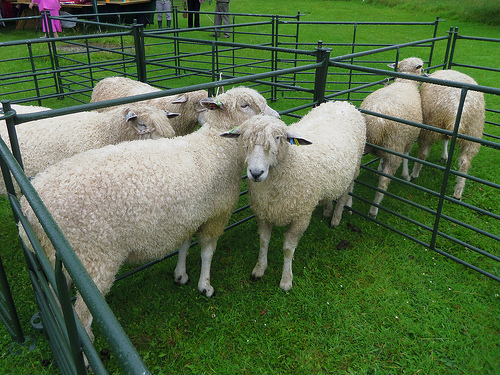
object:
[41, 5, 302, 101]
cage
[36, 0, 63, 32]
dress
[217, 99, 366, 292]
sheep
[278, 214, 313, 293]
front legs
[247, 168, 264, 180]
nose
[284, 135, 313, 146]
ear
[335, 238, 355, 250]
manure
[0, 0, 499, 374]
grass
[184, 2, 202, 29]
pants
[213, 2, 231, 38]
pants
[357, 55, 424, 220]
sheep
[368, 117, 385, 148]
tail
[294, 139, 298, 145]
tag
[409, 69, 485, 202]
sheep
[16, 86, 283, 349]
sheep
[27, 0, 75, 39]
person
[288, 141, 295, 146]
tag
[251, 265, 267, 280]
hooves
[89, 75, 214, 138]
sheep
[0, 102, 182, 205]
sheep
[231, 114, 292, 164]
hair